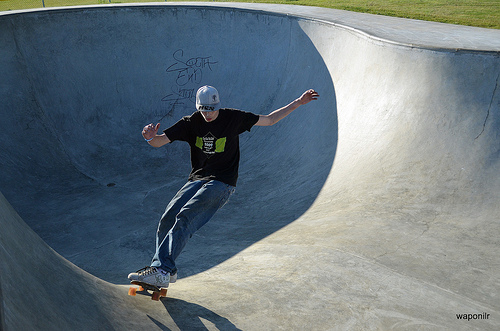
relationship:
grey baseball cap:
[200, 90, 213, 104] [190, 78, 227, 114]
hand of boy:
[135, 116, 164, 147] [145, 67, 285, 300]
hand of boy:
[293, 79, 321, 108] [145, 67, 285, 300]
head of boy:
[187, 80, 224, 127] [145, 67, 285, 300]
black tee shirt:
[217, 112, 243, 131] [171, 104, 257, 183]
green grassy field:
[433, 3, 484, 22] [1, 0, 499, 22]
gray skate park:
[339, 34, 424, 130] [13, 3, 473, 91]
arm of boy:
[247, 84, 335, 131] [145, 67, 285, 300]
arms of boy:
[136, 117, 194, 153] [145, 67, 285, 300]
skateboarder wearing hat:
[145, 67, 285, 300] [190, 78, 227, 114]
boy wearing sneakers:
[126, 82, 324, 289] [132, 253, 180, 289]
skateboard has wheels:
[127, 280, 178, 309] [121, 282, 160, 302]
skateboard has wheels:
[127, 280, 178, 309] [139, 282, 171, 293]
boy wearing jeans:
[126, 82, 324, 289] [145, 166, 229, 272]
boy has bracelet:
[126, 82, 324, 289] [141, 130, 161, 146]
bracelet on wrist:
[141, 130, 161, 146] [139, 127, 164, 145]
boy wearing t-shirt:
[126, 82, 324, 289] [171, 104, 257, 183]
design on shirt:
[192, 128, 234, 157] [171, 104, 257, 183]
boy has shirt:
[126, 82, 324, 289] [171, 104, 257, 183]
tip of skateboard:
[124, 279, 146, 289] [127, 280, 178, 309]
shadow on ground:
[249, 12, 353, 230] [252, 177, 370, 251]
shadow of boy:
[149, 288, 220, 331] [126, 82, 324, 289]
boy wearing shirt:
[126, 82, 324, 289] [171, 104, 257, 183]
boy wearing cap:
[126, 82, 324, 289] [190, 78, 227, 114]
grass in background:
[339, 0, 494, 25] [2, 1, 495, 63]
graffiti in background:
[149, 39, 225, 92] [2, 1, 495, 63]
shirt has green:
[171, 104, 257, 183] [194, 133, 229, 152]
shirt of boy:
[171, 104, 257, 183] [126, 82, 324, 289]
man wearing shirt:
[145, 67, 285, 300] [171, 104, 257, 183]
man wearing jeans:
[145, 67, 285, 300] [145, 166, 229, 272]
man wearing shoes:
[145, 67, 285, 300] [132, 253, 180, 289]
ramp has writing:
[233, 0, 455, 276] [149, 39, 225, 92]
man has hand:
[145, 67, 285, 300] [135, 116, 164, 147]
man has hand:
[145, 67, 285, 300] [293, 79, 321, 108]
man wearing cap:
[145, 67, 285, 300] [190, 78, 227, 114]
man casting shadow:
[145, 67, 285, 300] [149, 288, 220, 331]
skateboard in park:
[127, 280, 178, 309] [13, 3, 473, 91]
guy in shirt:
[145, 67, 285, 300] [171, 104, 257, 183]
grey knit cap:
[200, 90, 214, 105] [190, 78, 227, 114]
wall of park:
[302, 31, 408, 219] [13, 3, 473, 91]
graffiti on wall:
[149, 39, 225, 92] [302, 31, 408, 219]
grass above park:
[339, 0, 494, 25] [13, 3, 473, 91]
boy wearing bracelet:
[145, 67, 285, 300] [141, 130, 161, 146]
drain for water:
[104, 177, 124, 189] [97, 166, 123, 194]